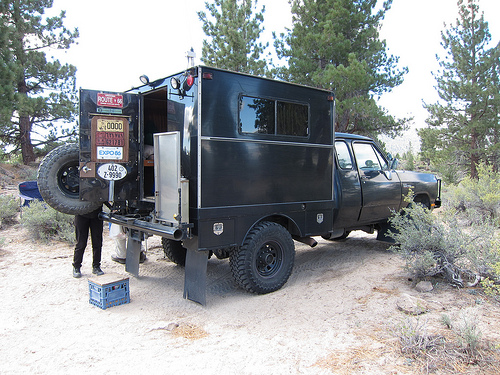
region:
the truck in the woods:
[62, 58, 484, 297]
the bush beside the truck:
[386, 192, 494, 275]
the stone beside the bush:
[388, 285, 440, 325]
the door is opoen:
[51, 70, 143, 192]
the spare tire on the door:
[37, 149, 104, 209]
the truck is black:
[47, 54, 489, 304]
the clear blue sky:
[113, 24, 160, 59]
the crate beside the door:
[79, 273, 153, 320]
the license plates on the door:
[88, 117, 133, 157]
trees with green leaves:
[213, 8, 380, 68]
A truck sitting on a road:
[25, 30, 457, 310]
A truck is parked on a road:
[36, 27, 472, 312]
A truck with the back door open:
[36, 50, 464, 322]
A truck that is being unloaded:
[36, 33, 463, 329]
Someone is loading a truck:
[37, 32, 462, 329]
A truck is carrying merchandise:
[25, 47, 480, 337]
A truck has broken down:
[30, 35, 475, 340]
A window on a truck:
[235, 100, 311, 140]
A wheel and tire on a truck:
[245, 220, 291, 291]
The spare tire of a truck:
[37, 142, 79, 213]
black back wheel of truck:
[228, 223, 293, 295]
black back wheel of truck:
[160, 235, 180, 262]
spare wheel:
[40, 148, 103, 211]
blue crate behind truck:
[89, 276, 131, 308]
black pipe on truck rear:
[106, 214, 185, 237]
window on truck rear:
[241, 90, 311, 138]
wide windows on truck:
[337, 140, 380, 173]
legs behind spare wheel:
[71, 217, 103, 279]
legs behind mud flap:
[112, 225, 127, 260]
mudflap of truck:
[180, 250, 206, 298]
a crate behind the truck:
[31, 76, 216, 312]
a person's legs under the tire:
[32, 140, 112, 280]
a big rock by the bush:
[385, 187, 478, 315]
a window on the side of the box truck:
[232, 88, 313, 144]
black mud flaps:
[117, 225, 215, 305]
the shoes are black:
[70, 260, 105, 276]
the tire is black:
[228, 217, 298, 294]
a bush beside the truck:
[40, 68, 496, 304]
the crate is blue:
[84, 269, 131, 310]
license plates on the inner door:
[86, 88, 135, 185]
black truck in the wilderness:
[73, 64, 447, 300]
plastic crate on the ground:
[86, 270, 136, 308]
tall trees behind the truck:
[0, 0, 499, 180]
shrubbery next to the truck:
[384, 158, 499, 296]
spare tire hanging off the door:
[34, 140, 107, 215]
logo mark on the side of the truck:
[209, 215, 227, 236]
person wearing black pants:
[68, 199, 108, 279]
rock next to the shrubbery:
[395, 287, 427, 317]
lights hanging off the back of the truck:
[138, 69, 199, 99]